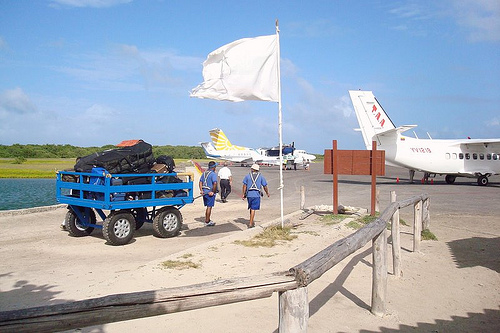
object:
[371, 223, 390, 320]
fence post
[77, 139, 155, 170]
bags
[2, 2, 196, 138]
sky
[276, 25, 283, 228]
pole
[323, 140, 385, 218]
sign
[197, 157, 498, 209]
runway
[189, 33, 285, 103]
flag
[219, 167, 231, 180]
shirt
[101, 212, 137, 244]
tire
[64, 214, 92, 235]
tire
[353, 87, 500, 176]
airplane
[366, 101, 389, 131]
words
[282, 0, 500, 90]
sky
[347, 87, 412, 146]
tail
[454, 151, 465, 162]
windows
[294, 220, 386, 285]
wooden fence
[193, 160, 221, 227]
man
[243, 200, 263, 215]
blue shorts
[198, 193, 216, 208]
blue shorts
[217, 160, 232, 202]
man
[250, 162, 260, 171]
hat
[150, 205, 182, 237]
tire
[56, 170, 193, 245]
trailer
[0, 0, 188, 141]
white clouds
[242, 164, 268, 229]
man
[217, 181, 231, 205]
pants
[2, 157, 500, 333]
ground